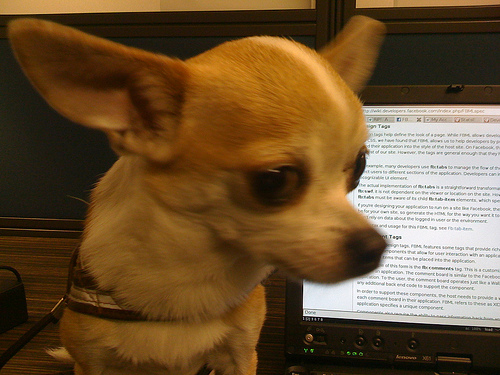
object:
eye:
[238, 157, 307, 207]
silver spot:
[49, 295, 74, 321]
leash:
[0, 242, 204, 372]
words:
[386, 231, 404, 242]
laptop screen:
[299, 104, 500, 333]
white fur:
[85, 193, 237, 312]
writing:
[348, 121, 500, 322]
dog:
[9, 14, 391, 371]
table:
[0, 230, 293, 374]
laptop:
[275, 78, 500, 374]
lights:
[307, 346, 317, 353]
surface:
[0, 236, 294, 374]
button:
[300, 333, 315, 347]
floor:
[0, 233, 291, 374]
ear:
[316, 10, 385, 99]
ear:
[0, 10, 174, 161]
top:
[360, 81, 496, 106]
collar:
[66, 261, 211, 328]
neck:
[60, 202, 257, 315]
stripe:
[235, 37, 354, 150]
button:
[407, 339, 419, 352]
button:
[370, 335, 383, 350]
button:
[351, 337, 366, 350]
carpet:
[0, 235, 74, 373]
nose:
[347, 226, 390, 271]